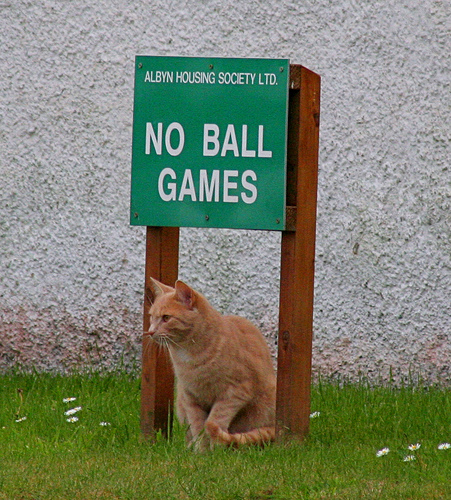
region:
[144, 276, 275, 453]
A cat is sitting in the grass.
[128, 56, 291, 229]
The sign is green.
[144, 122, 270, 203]
The sign reads No Ball Games.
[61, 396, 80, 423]
Flowers grow in the grass.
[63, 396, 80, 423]
The flowers are white.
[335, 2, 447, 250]
A wall is behind the sign.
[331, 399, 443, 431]
The grass is tall and green.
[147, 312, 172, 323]
The cat is looking to the left.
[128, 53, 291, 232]
green sign with white lettering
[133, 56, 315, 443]
sign on wooden posts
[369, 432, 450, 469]
little white flowers in the grass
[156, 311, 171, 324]
small orange eye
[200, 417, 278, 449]
tiger striped cat tail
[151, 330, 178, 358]
long white whiskers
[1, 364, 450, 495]
green grass with small white flowers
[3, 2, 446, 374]
rough grey wall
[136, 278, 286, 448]
the orange cat is looking at something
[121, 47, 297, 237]
green and white sign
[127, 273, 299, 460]
cat sitting in the grass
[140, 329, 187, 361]
white whiskers sticking out of the face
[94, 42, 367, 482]
cat sitting under the sign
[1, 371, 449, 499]
green grass on the ground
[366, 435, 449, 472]
white objects in the grass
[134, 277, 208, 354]
head turned to the side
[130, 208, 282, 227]
three bolts on the bottom of the sign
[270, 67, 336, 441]
wooden post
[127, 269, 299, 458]
A cat in the foreground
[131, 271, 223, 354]
A side view of a cat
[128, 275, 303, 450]
Cat is sitting in the grass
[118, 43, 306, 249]
A green sign in the foreground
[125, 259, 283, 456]
The cat is orange in color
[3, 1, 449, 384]
Background wall is gray in color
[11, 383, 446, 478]
White flowers in the grass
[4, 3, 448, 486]
Photo was taken in the daytime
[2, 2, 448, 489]
Photo was taken outdoors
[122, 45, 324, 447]
Two wooden poles are holding the sign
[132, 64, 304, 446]
sign on brown posts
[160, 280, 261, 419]
cat between wooden posts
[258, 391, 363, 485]
cat sits on grass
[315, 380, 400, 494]
green and thick grass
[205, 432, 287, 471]
cat has orange tail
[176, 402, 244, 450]
cat has orange paws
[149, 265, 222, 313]
cat has orange ears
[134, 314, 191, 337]
cat has pink nose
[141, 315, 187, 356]
cat has white whiskers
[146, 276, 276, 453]
Orange cat sitting in grass.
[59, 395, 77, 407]
White dandelion in the grass.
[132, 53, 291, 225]
Green sign saying No Ball Games.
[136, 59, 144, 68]
Small grey screw on green sign.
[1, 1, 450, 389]
Grey wall behind sign and cat.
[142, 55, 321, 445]
Wooden stand for green sign.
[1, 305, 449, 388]
Red paint on side of grey wall.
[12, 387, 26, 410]
Dandelion with no petals.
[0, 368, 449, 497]
Small patch of grass.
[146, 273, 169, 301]
left ear of the cat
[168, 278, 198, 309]
right ear of the cat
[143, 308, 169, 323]
eyeballs of the cat